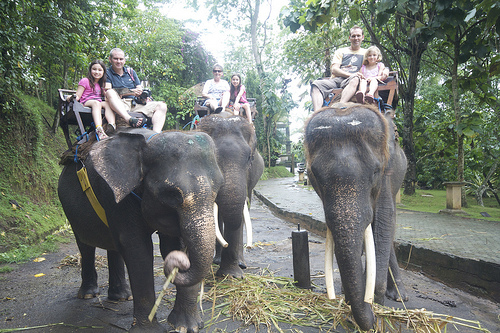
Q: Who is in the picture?
A: People.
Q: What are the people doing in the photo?
A: Riding elephants.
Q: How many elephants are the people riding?
A: Three.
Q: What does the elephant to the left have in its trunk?
A: A stick.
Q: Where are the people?
A: A national park.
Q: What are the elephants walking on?
A: Asphalt.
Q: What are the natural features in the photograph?
A: Trees.